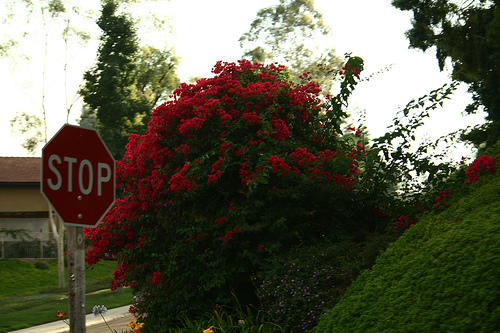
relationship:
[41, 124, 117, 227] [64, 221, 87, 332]
stop sign on post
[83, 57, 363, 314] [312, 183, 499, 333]
plant on hill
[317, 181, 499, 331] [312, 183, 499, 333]
ground cover on hill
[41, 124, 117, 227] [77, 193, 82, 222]
stop sign has bolts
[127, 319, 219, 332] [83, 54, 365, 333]
flowers below bush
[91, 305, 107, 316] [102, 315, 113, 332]
flower has stem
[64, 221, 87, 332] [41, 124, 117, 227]
post has stop sign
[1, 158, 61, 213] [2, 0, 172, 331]
roof in background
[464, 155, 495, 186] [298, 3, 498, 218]
bush in background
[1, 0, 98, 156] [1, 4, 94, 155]
tree has branches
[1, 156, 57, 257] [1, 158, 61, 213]
building has roof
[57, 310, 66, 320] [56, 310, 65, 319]
flower has petals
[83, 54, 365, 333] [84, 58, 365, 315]
bush has flowers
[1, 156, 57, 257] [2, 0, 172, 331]
house in background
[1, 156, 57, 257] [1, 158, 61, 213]
house has roof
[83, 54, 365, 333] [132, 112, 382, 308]
bush has leaves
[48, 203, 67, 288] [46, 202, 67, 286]
tree has trunk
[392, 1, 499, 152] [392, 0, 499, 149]
tree has leaves